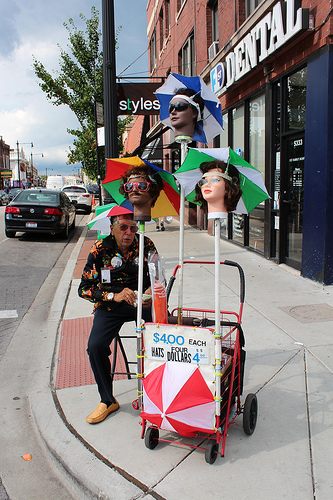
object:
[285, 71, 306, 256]
window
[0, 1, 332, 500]
scene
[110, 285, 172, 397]
chair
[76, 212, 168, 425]
man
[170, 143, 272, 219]
umbrella hats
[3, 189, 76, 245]
car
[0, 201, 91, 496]
street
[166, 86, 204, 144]
mannequin head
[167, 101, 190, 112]
sun glasses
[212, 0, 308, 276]
shop storefront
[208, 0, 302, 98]
sign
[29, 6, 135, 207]
tree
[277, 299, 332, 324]
man hole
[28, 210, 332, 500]
sidewalk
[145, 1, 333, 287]
building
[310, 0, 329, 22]
bricks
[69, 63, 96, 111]
leaves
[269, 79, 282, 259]
window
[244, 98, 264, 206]
window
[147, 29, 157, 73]
window